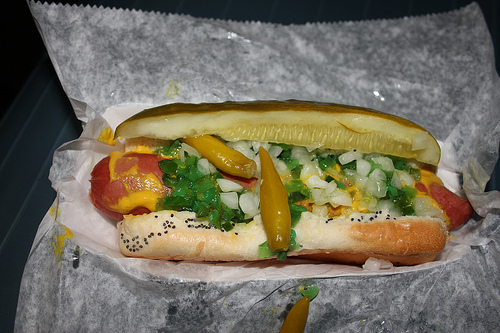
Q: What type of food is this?
A: Hot dog.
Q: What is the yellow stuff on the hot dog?
A: Mustard.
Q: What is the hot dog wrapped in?
A: Paper.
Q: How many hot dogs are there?
A: One.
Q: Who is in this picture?
A: No one.